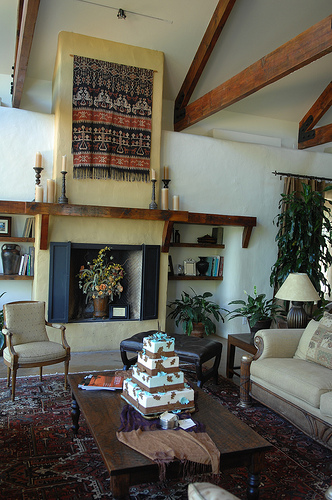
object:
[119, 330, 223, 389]
bench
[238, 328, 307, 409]
rolled arm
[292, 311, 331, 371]
pillow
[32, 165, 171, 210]
candlestick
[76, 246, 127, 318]
arrangement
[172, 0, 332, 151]
beam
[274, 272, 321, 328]
lamp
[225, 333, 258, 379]
table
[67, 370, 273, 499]
coffee table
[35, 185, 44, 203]
candles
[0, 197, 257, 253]
table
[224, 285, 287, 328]
plant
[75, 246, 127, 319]
potted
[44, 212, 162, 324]
fireplace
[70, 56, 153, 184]
fabric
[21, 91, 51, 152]
wall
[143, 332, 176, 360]
section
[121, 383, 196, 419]
section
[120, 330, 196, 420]
cake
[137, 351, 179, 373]
section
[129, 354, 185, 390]
section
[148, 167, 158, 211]
candle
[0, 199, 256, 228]
shelf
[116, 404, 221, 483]
blanket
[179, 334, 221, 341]
table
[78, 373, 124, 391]
book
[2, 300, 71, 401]
chair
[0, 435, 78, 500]
rug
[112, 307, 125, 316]
paper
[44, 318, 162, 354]
shelf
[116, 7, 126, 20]
light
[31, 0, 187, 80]
ceiling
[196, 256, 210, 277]
vase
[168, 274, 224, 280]
shelf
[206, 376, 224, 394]
ottoman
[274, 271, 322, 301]
shade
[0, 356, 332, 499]
rug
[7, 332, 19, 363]
armrests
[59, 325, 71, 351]
armrests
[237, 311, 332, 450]
couch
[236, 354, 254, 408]
leg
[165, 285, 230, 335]
plant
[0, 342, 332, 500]
floor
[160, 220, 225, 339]
nook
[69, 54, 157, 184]
hanging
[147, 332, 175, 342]
trimmings